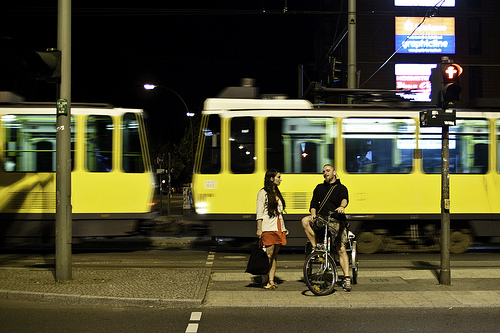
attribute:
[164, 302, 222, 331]
lines — white, painted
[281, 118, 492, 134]
lights — on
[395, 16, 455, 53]
sign — lit, promotional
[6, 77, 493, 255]
train — yellow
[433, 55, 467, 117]
traffic signal — electric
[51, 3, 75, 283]
pole — tall, metal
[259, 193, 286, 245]
dress — red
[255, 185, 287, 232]
jacket — white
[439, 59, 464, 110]
light — red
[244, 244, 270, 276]
backpack — black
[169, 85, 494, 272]
car — yellow, train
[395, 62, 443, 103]
ad — lighted, red, white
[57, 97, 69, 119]
sign — small, green, unreadable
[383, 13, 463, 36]
advertisement — lighted, blue, orange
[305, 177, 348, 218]
t-shirt — black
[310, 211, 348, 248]
shorts — brown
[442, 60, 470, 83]
red light — cross shaped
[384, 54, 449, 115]
sign — promotional, lit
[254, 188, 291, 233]
jacket — white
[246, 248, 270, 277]
bag — black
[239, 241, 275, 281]
bag — red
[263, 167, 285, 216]
hair — brown, woman's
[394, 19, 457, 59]
sign — blue, orange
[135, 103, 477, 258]
car — train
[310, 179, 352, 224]
shirt — man's, black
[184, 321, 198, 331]
line — white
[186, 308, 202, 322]
line — white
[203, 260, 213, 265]
line — white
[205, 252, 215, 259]
line — white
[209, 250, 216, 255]
line — white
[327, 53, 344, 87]
light — lit, green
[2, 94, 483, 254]
commuter train — yellow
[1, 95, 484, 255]
train — yellow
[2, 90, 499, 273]
trains — passing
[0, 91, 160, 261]
car — yellow, train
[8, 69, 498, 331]
corner — street